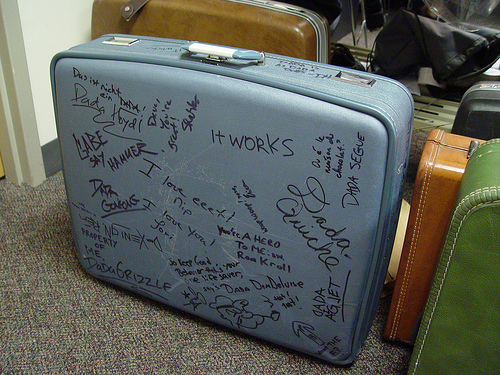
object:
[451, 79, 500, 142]
briefcase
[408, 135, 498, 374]
suitcase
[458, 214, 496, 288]
leather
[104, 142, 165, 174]
writing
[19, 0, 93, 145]
wall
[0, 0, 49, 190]
door frame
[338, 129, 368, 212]
writing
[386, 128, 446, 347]
stitching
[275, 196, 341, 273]
writing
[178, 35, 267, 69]
handle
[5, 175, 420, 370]
ground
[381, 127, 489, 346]
brown suitcase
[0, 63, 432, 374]
carpet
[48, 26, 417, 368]
briefcase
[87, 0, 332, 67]
luggage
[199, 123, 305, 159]
signatures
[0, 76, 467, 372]
floor